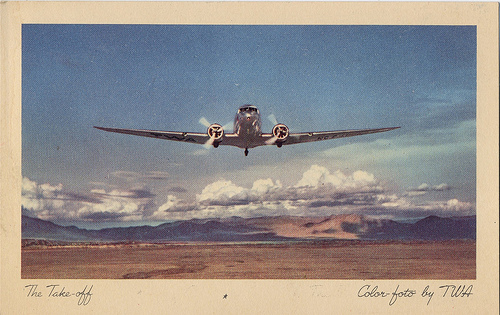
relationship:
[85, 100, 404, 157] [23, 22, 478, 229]
airplane flying in sky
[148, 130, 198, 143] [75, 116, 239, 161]
twa on wing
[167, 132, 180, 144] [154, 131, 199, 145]
'w' on wing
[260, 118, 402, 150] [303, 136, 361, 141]
wing with writing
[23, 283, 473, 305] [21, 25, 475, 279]
writing on picture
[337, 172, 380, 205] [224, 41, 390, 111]
cloud in sky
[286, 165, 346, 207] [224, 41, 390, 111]
cloud in sky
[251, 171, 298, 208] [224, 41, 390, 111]
cloud in sky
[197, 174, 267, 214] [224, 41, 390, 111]
cloud in sky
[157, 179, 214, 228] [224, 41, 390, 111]
cloud in sky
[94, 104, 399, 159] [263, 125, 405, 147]
plane has set of wings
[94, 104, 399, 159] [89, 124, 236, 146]
plane has set of wings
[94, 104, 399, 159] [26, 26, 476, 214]
plane in sky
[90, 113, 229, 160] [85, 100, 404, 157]
wing on airplane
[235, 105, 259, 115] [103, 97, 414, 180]
window on plane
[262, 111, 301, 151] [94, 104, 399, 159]
propeller on plane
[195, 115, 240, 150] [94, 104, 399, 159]
propeller on plane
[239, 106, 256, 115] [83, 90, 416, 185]
windshield on plane